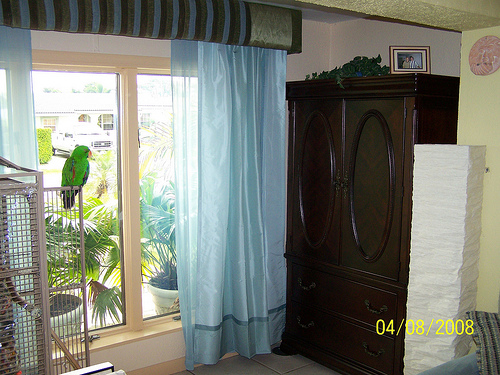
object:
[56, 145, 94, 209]
bird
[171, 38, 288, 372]
curtain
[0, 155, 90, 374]
cage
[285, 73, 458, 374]
dresser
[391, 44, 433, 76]
photo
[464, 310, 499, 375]
pillow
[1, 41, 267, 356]
window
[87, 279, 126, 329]
piece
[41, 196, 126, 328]
greenery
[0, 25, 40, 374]
curtain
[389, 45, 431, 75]
frame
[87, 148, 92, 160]
beak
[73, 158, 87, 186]
feather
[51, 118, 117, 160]
vehicle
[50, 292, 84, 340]
planter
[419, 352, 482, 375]
sofa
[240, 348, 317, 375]
tile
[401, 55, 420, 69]
couple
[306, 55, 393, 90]
plant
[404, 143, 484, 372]
lamp shade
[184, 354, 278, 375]
tile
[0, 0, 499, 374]
room scene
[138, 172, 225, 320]
plant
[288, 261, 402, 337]
drawer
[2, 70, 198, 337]
outside